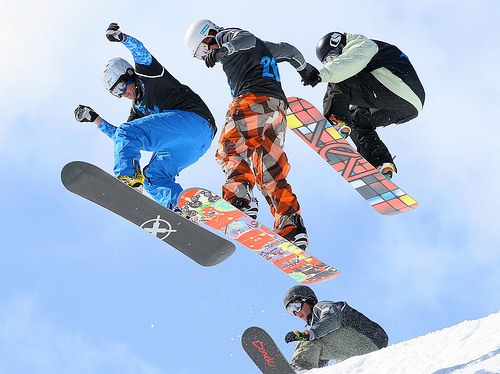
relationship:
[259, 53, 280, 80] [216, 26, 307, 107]
number on shirt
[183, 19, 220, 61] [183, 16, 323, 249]
helmet on skier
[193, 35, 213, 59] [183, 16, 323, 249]
googles on skier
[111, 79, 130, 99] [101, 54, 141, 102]
googles on a head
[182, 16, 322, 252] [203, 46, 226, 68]
man in a glove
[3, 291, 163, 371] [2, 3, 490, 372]
clouds in sky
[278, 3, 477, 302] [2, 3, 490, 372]
clouds in sky